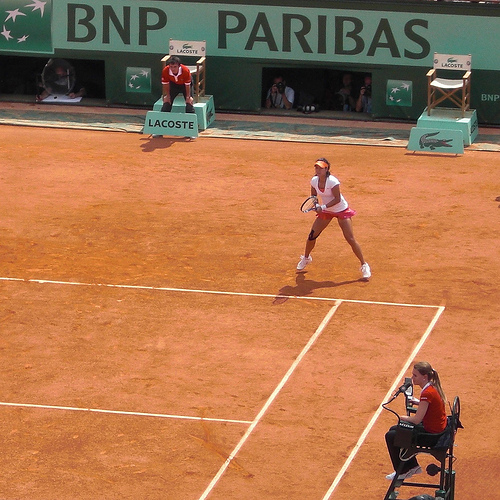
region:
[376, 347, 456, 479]
The woman is sitting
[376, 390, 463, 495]
The chair is tall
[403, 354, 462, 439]
Woman wearing a red shirt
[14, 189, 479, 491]
Brown court with white lines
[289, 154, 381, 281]
The woman is holding a tennis racket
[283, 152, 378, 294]
The woman is playing tennis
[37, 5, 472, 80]
The wall is green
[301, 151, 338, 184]
The woman is wearing a hat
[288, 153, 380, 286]
The woman has red shorts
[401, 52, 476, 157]
White chair on a green block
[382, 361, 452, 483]
Head Female Tennis umpire in red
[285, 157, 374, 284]
Female Tennis player in white top and pink skirt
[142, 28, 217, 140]
Center line judge standing and leaning in his box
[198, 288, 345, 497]
Tennis court's singles sideline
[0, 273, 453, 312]
Tennis courts baseline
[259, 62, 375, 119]
Right media and photographer dugout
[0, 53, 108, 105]
Left media and photographer dugout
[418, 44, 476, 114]
Vacant lacoste sideline judges chair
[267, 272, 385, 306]
Female tennis player's shadow on court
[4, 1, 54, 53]
The largest BNP Paribas logo of four stars in a circle in upper left corner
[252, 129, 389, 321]
a woman playing tennis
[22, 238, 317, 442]
white lines on the ground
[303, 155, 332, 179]
woman wearing a visor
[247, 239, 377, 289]
the woman is jumping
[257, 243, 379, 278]
the sneakers are white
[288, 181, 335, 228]
woman is holding a tennis racket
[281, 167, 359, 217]
the shirt is white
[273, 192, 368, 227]
woman is wearing a skirt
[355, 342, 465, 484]
woman sitting in a chair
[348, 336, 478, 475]
woman is talking into a mic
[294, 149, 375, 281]
woman wearing a white shirt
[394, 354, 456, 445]
woman wearing red shirt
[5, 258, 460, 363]
white lines on dirt ground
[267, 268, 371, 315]
shadow of woman on ground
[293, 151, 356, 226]
woman wearing red skirt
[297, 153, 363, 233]
woman wearing a visor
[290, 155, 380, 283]
woman wearing white shoes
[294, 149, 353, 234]
woman holding tennis racket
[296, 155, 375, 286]
woman playing tennis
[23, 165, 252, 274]
orange dirt floor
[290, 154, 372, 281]
woman is playing tennis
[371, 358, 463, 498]
referee in tall chair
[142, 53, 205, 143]
guy standing above blue chair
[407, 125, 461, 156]
image of alligator on blue chair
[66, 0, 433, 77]
BNP PARIBAS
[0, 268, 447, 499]
tennis court is red dirt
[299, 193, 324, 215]
woman is holding tennis racket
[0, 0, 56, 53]
large green logo with white stars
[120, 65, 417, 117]
two small logos on wall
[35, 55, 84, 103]
man in bunker is holding tv camera